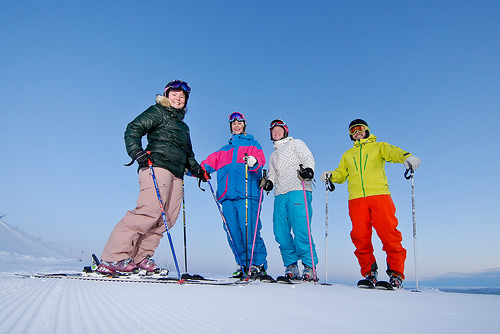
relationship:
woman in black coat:
[88, 50, 202, 285] [122, 94, 203, 179]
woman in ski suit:
[202, 110, 272, 273] [183, 133, 273, 283]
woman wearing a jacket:
[246, 109, 326, 299] [261, 141, 311, 194]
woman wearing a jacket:
[310, 108, 447, 322] [328, 140, 405, 202]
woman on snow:
[95, 78, 213, 277] [52, 282, 346, 329]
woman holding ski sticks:
[95, 78, 213, 277] [130, 150, 434, 303]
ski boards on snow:
[33, 261, 426, 298] [95, 277, 455, 329]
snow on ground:
[32, 295, 271, 318] [105, 292, 224, 328]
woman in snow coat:
[318, 117, 423, 290] [326, 133, 413, 203]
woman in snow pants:
[318, 117, 423, 290] [345, 194, 407, 278]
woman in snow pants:
[257, 117, 319, 281] [267, 188, 319, 274]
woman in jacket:
[257, 117, 319, 281] [261, 141, 311, 194]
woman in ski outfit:
[184, 110, 270, 280] [202, 138, 272, 273]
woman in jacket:
[95, 78, 213, 277] [109, 102, 201, 178]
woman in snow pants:
[95, 78, 213, 277] [97, 167, 187, 265]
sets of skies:
[62, 252, 432, 305] [55, 254, 432, 307]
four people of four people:
[86, 79, 421, 289] [86, 79, 421, 289]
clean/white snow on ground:
[7, 281, 315, 331] [23, 278, 469, 328]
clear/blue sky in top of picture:
[5, 2, 343, 67] [3, 0, 484, 331]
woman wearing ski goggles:
[318, 117, 423, 290] [346, 120, 366, 133]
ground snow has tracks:
[33, 280, 157, 331] [5, 275, 51, 332]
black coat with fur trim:
[122, 98, 203, 178] [153, 95, 173, 107]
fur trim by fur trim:
[153, 95, 173, 107] [153, 94, 173, 108]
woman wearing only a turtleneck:
[257, 117, 319, 281] [271, 137, 314, 196]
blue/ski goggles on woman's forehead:
[225, 111, 244, 122] [226, 109, 247, 138]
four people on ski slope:
[86, 79, 421, 289] [3, 281, 454, 328]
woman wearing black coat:
[95, 78, 213, 277] [122, 94, 203, 179]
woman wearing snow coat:
[318, 117, 423, 290] [320, 138, 410, 204]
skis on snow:
[411, 220, 419, 290] [276, 280, 386, 331]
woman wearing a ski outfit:
[318, 117, 423, 290] [199, 133, 268, 274]